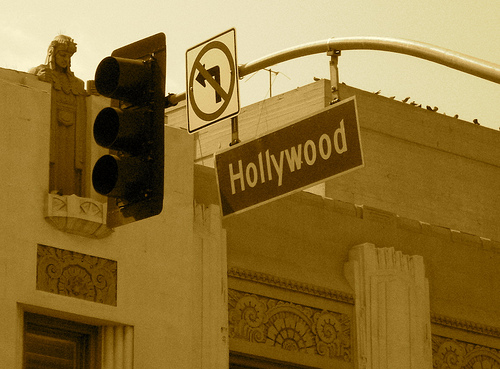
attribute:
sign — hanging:
[213, 95, 365, 220]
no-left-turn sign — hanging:
[184, 27, 240, 134]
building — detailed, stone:
[2, 69, 500, 368]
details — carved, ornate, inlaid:
[35, 242, 118, 308]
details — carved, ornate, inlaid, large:
[226, 287, 358, 368]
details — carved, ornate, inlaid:
[431, 332, 499, 369]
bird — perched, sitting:
[472, 118, 480, 127]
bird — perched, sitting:
[426, 105, 440, 114]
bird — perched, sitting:
[402, 95, 411, 105]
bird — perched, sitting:
[311, 75, 322, 82]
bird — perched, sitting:
[372, 89, 382, 95]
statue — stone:
[32, 34, 98, 196]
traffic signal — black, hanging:
[93, 33, 166, 230]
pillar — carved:
[344, 243, 433, 369]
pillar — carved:
[195, 203, 229, 369]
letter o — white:
[302, 138, 317, 167]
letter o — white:
[317, 132, 332, 161]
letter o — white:
[247, 161, 258, 188]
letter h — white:
[227, 160, 246, 196]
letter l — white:
[256, 150, 267, 184]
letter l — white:
[263, 148, 273, 182]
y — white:
[270, 150, 285, 188]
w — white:
[282, 142, 303, 172]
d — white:
[332, 119, 348, 154]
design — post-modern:
[226, 262, 359, 308]